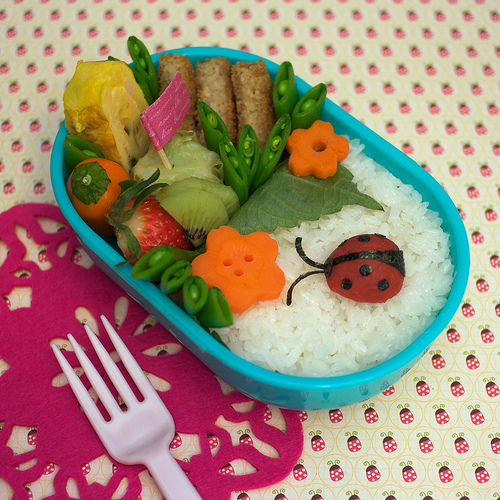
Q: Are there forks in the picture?
A: Yes, there is a fork.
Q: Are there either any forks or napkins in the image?
A: Yes, there is a fork.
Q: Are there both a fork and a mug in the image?
A: No, there is a fork but no mugs.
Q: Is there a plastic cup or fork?
A: Yes, there is a plastic fork.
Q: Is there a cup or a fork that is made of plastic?
A: Yes, the fork is made of plastic.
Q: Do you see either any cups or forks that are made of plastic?
A: Yes, the fork is made of plastic.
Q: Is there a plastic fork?
A: Yes, there is a fork that is made of plastic.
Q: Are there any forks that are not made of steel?
A: Yes, there is a fork that is made of plastic.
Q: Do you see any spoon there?
A: No, there are no spoons.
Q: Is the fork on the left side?
A: Yes, the fork is on the left of the image.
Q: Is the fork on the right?
A: No, the fork is on the left of the image.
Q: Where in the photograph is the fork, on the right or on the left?
A: The fork is on the left of the image.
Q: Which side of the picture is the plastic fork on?
A: The fork is on the left of the image.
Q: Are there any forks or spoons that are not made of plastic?
A: No, there is a fork but it is made of plastic.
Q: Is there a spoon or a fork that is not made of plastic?
A: No, there is a fork but it is made of plastic.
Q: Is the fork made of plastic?
A: Yes, the fork is made of plastic.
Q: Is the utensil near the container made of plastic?
A: Yes, the fork is made of plastic.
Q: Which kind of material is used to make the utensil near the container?
A: The fork is made of plastic.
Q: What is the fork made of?
A: The fork is made of plastic.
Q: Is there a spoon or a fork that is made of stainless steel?
A: No, there is a fork but it is made of plastic.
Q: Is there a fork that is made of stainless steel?
A: No, there is a fork but it is made of plastic.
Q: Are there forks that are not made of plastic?
A: No, there is a fork but it is made of plastic.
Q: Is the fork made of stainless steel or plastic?
A: The fork is made of plastic.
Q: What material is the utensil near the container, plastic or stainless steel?
A: The fork is made of plastic.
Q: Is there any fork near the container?
A: Yes, there is a fork near the container.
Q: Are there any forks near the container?
A: Yes, there is a fork near the container.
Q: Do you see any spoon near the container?
A: No, there is a fork near the container.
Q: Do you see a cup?
A: No, there are no cups.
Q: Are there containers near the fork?
A: Yes, there is a container near the fork.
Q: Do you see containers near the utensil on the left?
A: Yes, there is a container near the fork.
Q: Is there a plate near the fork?
A: No, there is a container near the fork.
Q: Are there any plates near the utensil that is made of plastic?
A: No, there is a container near the fork.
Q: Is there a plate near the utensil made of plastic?
A: No, there is a container near the fork.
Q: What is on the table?
A: The container is on the table.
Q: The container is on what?
A: The container is on the table.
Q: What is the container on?
A: The container is on the table.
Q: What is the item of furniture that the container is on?
A: The piece of furniture is a table.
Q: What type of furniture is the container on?
A: The container is on the table.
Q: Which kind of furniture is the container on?
A: The container is on the table.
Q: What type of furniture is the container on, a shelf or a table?
A: The container is on a table.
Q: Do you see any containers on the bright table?
A: Yes, there is a container on the table.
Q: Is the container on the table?
A: Yes, the container is on the table.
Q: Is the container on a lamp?
A: No, the container is on the table.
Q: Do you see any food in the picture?
A: Yes, there is food.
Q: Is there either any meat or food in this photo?
A: Yes, there is food.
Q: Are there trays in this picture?
A: No, there are no trays.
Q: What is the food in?
A: The food is in the container.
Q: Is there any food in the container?
A: Yes, there is food in the container.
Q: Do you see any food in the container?
A: Yes, there is food in the container.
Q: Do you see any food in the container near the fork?
A: Yes, there is food in the container.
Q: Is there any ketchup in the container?
A: No, there is food in the container.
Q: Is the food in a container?
A: Yes, the food is in a container.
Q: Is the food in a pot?
A: No, the food is in a container.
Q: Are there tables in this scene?
A: Yes, there is a table.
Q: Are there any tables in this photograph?
A: Yes, there is a table.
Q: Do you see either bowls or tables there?
A: Yes, there is a table.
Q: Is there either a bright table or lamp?
A: Yes, there is a bright table.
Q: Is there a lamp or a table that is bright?
A: Yes, the table is bright.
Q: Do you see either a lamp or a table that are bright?
A: Yes, the table is bright.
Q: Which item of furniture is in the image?
A: The piece of furniture is a table.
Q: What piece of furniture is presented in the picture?
A: The piece of furniture is a table.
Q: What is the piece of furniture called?
A: The piece of furniture is a table.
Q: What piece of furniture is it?
A: The piece of furniture is a table.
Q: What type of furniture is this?
A: This is a table.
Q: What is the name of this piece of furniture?
A: This is a table.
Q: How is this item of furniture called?
A: This is a table.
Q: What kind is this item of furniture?
A: This is a table.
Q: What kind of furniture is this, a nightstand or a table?
A: This is a table.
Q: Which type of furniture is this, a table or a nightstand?
A: This is a table.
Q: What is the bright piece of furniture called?
A: The piece of furniture is a table.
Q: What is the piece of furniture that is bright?
A: The piece of furniture is a table.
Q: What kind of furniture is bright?
A: The furniture is a table.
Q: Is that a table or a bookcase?
A: That is a table.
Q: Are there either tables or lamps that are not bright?
A: No, there is a table but it is bright.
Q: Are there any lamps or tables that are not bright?
A: No, there is a table but it is bright.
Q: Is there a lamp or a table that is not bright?
A: No, there is a table but it is bright.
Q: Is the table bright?
A: Yes, the table is bright.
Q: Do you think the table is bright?
A: Yes, the table is bright.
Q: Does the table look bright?
A: Yes, the table is bright.